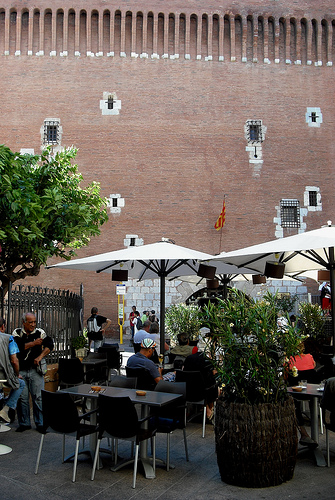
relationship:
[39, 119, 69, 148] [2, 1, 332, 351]
window on building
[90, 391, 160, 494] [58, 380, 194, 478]
chair at table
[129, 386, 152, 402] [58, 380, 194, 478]
bowl on top of table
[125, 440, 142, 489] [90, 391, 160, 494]
leg on chair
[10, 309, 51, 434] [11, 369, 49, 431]
man wearing blue jeans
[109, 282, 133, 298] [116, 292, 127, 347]
sign on pole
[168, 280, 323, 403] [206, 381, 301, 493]
plant in barrel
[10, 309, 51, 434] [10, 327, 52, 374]
man wearing shirt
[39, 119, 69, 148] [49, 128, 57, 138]
window has bars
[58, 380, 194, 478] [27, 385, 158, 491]
table with chairs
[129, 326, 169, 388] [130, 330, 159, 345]
man wearing cap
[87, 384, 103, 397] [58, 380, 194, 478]
ashtray on table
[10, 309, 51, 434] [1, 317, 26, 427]
man talking to man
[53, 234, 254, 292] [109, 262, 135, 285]
umbrella has lights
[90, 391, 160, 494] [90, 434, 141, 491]
chair has legs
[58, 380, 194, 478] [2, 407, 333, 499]
table on sidewalk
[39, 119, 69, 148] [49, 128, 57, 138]
window with bars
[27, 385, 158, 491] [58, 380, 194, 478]
chairs at table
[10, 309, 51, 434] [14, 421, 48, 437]
man wearing shoes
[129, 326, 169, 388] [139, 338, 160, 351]
man wearing cap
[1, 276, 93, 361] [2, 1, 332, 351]
fence near building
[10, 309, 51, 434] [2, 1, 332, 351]
man by building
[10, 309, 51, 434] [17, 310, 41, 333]
man has hair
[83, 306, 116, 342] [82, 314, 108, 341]
person wearing shirt